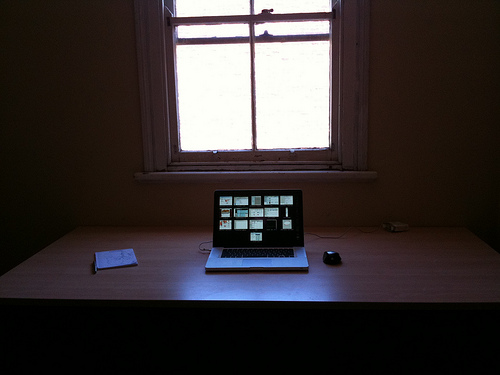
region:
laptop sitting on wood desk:
[216, 192, 303, 272]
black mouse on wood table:
[315, 246, 338, 266]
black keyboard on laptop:
[206, 240, 306, 268]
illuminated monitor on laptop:
[213, 187, 300, 252]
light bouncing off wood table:
[185, 266, 332, 306]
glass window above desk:
[174, 3, 331, 159]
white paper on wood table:
[85, 245, 142, 277]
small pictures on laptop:
[221, 192, 291, 240]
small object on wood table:
[387, 213, 404, 234]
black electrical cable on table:
[305, 220, 350, 250]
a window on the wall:
[173, 5, 333, 157]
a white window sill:
[134, 7, 368, 179]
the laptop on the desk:
[211, 191, 312, 271]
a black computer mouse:
[323, 250, 340, 265]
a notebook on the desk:
[92, 248, 137, 270]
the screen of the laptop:
[216, 192, 302, 244]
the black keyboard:
[218, 248, 296, 260]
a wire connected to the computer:
[312, 218, 406, 237]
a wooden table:
[7, 220, 498, 327]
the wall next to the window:
[20, 10, 132, 217]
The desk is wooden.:
[61, 223, 496, 305]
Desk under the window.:
[128, 3, 380, 185]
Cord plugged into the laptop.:
[188, 238, 220, 263]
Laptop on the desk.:
[208, 187, 318, 279]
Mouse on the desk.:
[318, 244, 350, 273]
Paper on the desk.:
[95, 248, 142, 276]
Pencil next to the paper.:
[83, 252, 111, 283]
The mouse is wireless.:
[321, 237, 353, 277]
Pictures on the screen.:
[218, 192, 298, 243]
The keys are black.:
[218, 241, 298, 263]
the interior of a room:
[0, 0, 499, 374]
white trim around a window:
[132, 0, 377, 180]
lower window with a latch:
[164, 8, 339, 163]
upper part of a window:
[164, 0, 340, 45]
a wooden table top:
[0, 224, 499, 309]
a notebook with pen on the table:
[92, 247, 137, 272]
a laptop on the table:
[204, 188, 309, 273]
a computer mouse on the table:
[322, 249, 342, 265]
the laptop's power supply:
[197, 219, 409, 252]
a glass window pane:
[175, 22, 252, 152]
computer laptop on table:
[190, 167, 320, 279]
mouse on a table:
[317, 231, 349, 270]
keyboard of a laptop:
[200, 235, 310, 273]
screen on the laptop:
[210, 188, 307, 242]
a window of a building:
[163, 7, 350, 171]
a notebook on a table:
[85, 238, 142, 271]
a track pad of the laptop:
[239, 253, 276, 270]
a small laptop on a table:
[189, 178, 319, 288]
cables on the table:
[322, 198, 426, 244]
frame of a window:
[155, 20, 354, 158]